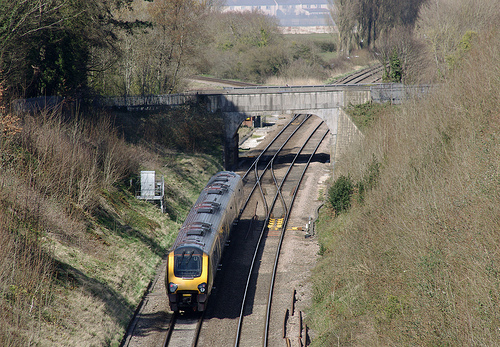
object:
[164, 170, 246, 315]
train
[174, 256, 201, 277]
windshield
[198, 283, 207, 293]
light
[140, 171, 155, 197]
box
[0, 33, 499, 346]
ground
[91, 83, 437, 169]
bridge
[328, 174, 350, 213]
bush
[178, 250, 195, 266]
wipers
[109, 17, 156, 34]
leaves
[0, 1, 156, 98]
tree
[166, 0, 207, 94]
tree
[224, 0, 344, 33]
town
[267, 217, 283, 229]
spot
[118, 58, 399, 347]
gravel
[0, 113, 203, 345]
weeds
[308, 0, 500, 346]
hill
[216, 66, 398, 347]
track